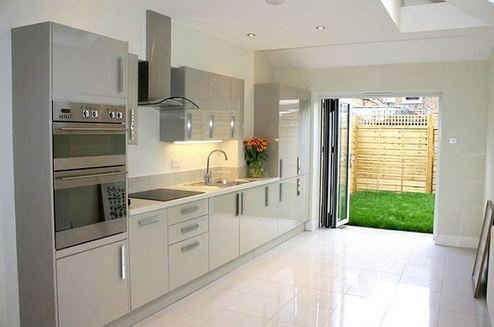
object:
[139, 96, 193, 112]
overhead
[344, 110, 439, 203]
privacy fence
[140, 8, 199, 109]
vent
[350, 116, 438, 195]
fence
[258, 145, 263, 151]
flower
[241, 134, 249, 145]
flower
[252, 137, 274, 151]
flower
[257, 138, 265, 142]
flower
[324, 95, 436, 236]
door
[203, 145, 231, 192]
faucet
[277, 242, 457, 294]
floor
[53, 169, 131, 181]
handle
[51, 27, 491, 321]
cabinets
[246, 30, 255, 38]
lights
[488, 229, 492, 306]
cabinet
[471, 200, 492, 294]
mirror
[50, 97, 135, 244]
stove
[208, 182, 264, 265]
cabinet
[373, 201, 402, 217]
green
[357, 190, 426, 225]
grass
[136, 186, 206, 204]
stove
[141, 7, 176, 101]
overhead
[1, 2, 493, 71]
ceiling